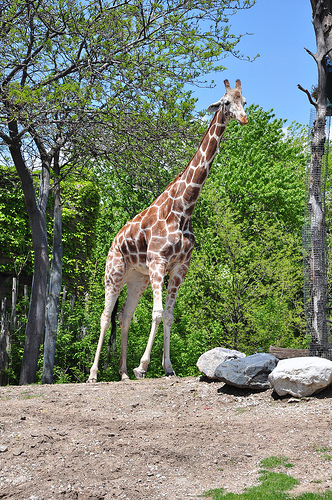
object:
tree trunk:
[296, 4, 332, 349]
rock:
[196, 347, 245, 380]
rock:
[268, 355, 332, 398]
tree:
[40, 49, 107, 382]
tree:
[0, 0, 261, 380]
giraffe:
[86, 78, 249, 382]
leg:
[160, 262, 187, 375]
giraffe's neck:
[171, 109, 225, 226]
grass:
[197, 455, 330, 498]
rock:
[212, 355, 277, 388]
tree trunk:
[19, 202, 49, 384]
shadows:
[5, 274, 51, 385]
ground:
[1, 354, 331, 498]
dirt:
[3, 374, 330, 493]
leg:
[91, 251, 124, 377]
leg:
[118, 274, 141, 379]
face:
[226, 89, 245, 121]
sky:
[220, 39, 307, 76]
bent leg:
[139, 269, 163, 376]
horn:
[235, 78, 241, 89]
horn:
[224, 78, 232, 90]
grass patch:
[194, 453, 326, 498]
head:
[221, 78, 247, 126]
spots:
[126, 222, 144, 239]